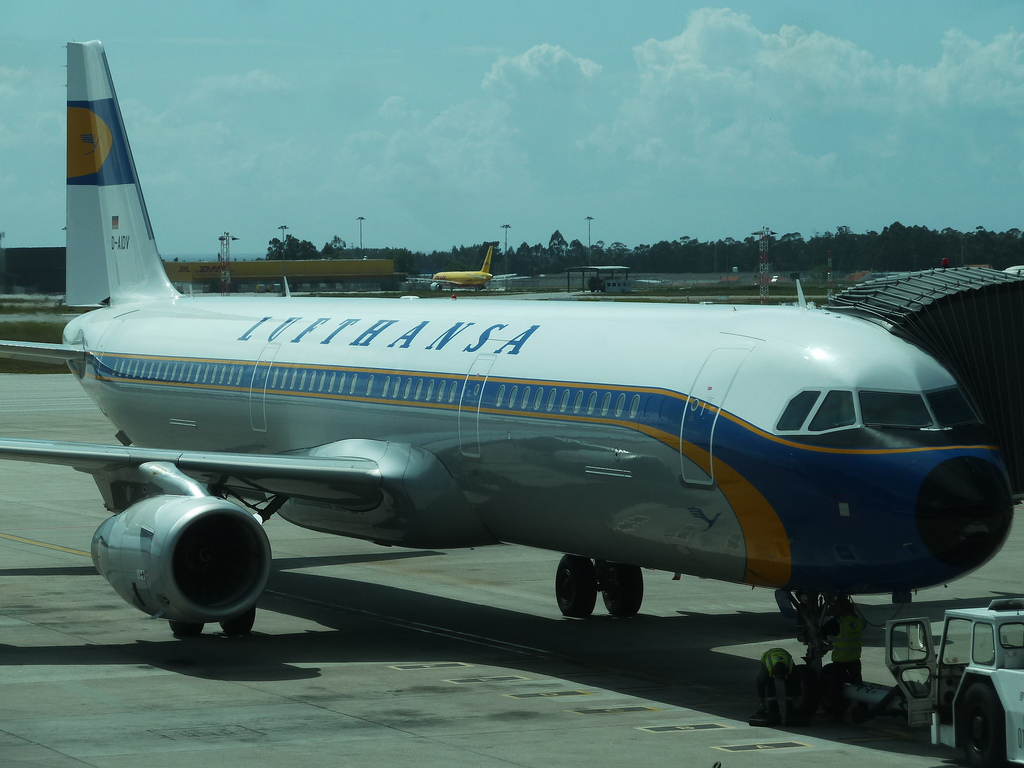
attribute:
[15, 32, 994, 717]
plane — yellow, tip